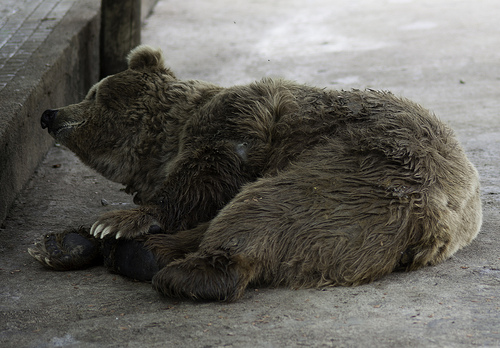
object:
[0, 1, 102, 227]
floor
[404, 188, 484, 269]
tail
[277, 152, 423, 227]
fur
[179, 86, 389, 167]
fur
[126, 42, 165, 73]
ear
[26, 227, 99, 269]
paw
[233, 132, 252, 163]
wound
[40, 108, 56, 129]
nose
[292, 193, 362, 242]
fur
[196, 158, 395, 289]
leg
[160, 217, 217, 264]
leg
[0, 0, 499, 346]
road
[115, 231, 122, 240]
claw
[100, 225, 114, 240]
claw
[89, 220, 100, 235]
claw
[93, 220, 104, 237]
claw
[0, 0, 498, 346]
ground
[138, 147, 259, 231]
legs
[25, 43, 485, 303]
bear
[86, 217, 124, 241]
claws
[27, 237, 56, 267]
claws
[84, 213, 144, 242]
paw